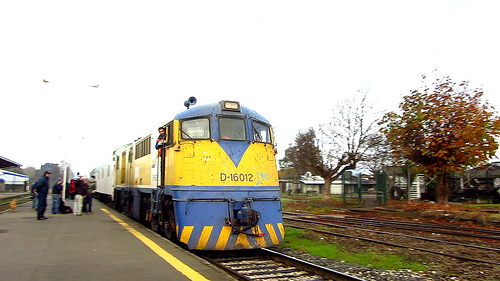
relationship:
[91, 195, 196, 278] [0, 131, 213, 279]
strip on platform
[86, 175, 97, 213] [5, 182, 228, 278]
man standing on platform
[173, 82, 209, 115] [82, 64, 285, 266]
horn on train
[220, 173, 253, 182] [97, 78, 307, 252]
d-16012 on engine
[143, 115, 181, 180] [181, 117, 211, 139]
man leaning out engine window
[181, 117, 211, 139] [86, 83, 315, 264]
engine window of engine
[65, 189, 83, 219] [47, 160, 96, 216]
pants worn by man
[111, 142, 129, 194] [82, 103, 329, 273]
door to car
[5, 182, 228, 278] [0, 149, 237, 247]
platform at station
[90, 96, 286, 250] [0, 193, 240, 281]
car parked at platform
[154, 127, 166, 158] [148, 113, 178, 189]
man on door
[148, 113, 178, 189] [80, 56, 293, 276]
door of train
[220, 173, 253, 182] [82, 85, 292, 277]
d-16012 of train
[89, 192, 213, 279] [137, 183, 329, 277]
line on side railroad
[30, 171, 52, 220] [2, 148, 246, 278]
man on platform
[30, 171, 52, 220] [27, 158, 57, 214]
man wears clothes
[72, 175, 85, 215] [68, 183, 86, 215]
man wears pants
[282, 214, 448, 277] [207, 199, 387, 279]
grass near railroad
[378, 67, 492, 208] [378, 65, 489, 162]
tree with leaves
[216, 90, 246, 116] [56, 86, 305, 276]
light in top of train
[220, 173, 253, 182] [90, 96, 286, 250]
d-16012 in front of car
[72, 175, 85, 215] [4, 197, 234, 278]
man standing on platform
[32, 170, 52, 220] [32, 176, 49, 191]
man wearing jacket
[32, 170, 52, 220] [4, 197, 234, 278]
man on platform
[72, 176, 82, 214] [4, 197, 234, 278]
man on platform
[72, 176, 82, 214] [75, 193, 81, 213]
man wearing pants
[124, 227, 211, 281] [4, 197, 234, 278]
line painted on platform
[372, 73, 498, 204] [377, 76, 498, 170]
tree with leaves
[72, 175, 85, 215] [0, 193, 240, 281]
man waiting on platform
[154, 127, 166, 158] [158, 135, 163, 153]
man wearing vest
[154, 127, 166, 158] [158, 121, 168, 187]
man leaing out engine window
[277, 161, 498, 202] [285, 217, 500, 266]
houses near railroad